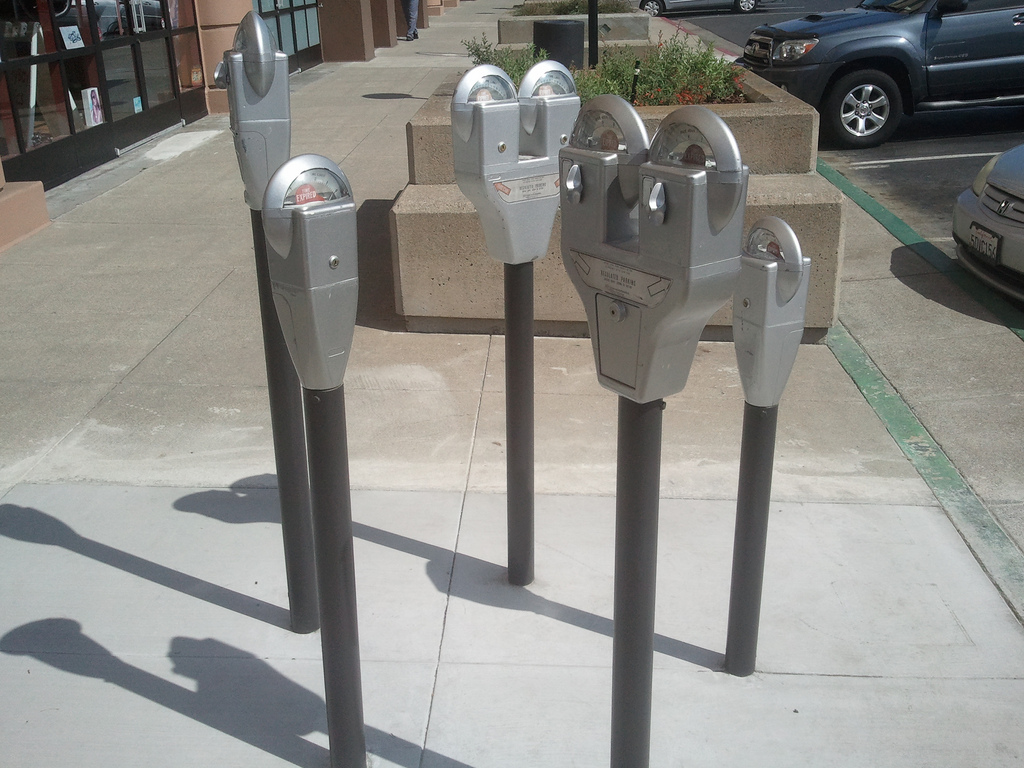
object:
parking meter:
[722, 216, 812, 677]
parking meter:
[262, 152, 368, 768]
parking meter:
[222, 8, 291, 211]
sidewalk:
[0, 66, 1024, 768]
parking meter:
[558, 95, 749, 406]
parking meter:
[733, 215, 812, 406]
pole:
[722, 402, 777, 678]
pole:
[250, 209, 319, 634]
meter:
[558, 92, 747, 765]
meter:
[262, 152, 368, 768]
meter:
[214, 11, 323, 634]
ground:
[0, 0, 1022, 768]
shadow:
[0, 502, 295, 628]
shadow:
[172, 471, 727, 667]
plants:
[455, 66, 772, 107]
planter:
[449, 60, 811, 405]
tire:
[822, 67, 904, 149]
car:
[742, 0, 1022, 147]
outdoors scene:
[0, 0, 1024, 768]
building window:
[0, 2, 211, 193]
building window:
[165, 25, 208, 125]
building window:
[99, 37, 145, 123]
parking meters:
[221, 11, 810, 768]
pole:
[607, 396, 664, 768]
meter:
[558, 93, 749, 404]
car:
[948, 141, 1024, 305]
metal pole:
[723, 402, 778, 678]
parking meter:
[451, 59, 580, 587]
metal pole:
[506, 263, 534, 586]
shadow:
[0, 616, 480, 768]